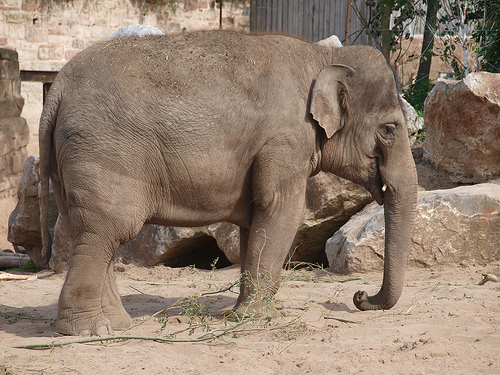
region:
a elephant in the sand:
[29, 31, 431, 340]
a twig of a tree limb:
[20, 256, 303, 352]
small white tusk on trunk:
[377, 172, 395, 206]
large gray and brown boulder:
[377, 72, 489, 293]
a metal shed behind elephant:
[234, 1, 402, 42]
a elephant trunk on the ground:
[347, 150, 445, 320]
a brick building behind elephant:
[15, 1, 170, 68]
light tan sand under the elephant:
[42, 314, 457, 364]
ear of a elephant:
[308, 57, 349, 152]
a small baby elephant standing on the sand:
[13, 26, 455, 346]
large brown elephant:
[25, 27, 430, 356]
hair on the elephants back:
[73, 30, 326, 53]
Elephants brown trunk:
[351, 149, 418, 311]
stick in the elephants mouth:
[380, 175, 390, 199]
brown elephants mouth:
[366, 153, 387, 203]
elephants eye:
[374, 119, 399, 140]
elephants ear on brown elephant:
[300, 56, 356, 145]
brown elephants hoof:
[56, 305, 116, 340]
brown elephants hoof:
[231, 287, 272, 326]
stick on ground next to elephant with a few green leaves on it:
[13, 224, 348, 356]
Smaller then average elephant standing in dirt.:
[38, 28, 416, 338]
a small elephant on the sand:
[23, 19, 423, 348]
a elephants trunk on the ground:
[352, 167, 418, 324]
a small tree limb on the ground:
[32, 275, 303, 365]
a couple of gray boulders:
[325, 89, 499, 299]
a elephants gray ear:
[303, 58, 357, 139]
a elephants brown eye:
[375, 118, 402, 147]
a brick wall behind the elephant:
[19, 0, 129, 70]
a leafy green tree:
[400, 0, 489, 104]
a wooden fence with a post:
[15, 62, 77, 106]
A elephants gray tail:
[30, 96, 81, 270]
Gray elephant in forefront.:
[37, 32, 419, 341]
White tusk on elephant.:
[378, 181, 388, 193]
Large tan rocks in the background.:
[408, 73, 494, 261]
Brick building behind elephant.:
[0, 2, 245, 264]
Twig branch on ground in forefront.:
[12, 266, 300, 372]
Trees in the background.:
[366, 1, 497, 114]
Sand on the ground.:
[4, 260, 496, 372]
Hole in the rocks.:
[158, 232, 230, 267]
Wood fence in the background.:
[252, 1, 390, 53]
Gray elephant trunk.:
[353, 90, 419, 317]